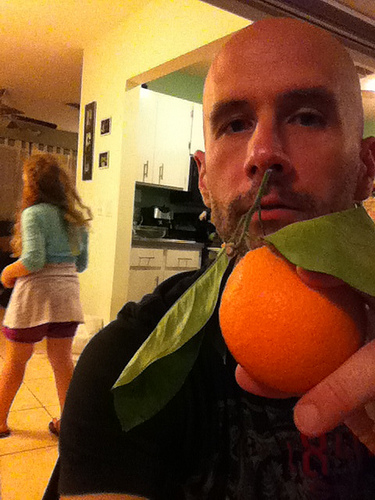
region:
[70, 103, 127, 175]
pictures on yellow wall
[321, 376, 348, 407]
ridges in man's finger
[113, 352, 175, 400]
edge of green leaf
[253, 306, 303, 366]
small grooves in orange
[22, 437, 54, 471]
tiles on floor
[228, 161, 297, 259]
stem of green leaf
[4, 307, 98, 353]
woman wearing purple shorts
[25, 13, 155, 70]
ridge in yellow ceiling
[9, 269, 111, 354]
woman wearing gray skirt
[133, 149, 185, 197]
the gold handle on yellow cabinet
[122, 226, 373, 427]
An orange with leaves on the stem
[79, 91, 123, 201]
Three pictures on the wall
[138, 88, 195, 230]
White cabinets on a blue wall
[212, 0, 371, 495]
A man with a black shirt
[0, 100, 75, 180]
White curtains are hanging in the room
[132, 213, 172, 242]
A clear bowl sits on the counter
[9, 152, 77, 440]
A woman in pink is walking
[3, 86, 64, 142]
The room has a ceiling fan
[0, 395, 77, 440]
The woman is wearing sandles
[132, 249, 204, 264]
The cabinets have silver handles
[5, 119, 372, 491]
The picture has an orange in it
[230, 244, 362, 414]
The orange is orange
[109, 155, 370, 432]
The orange has leaves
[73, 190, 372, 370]
The orange has green leaves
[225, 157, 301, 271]
The orange has a stem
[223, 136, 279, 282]
The orange has a green stem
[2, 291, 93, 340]
The girl is wearing shorts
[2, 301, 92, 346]
The girl is wearing magenta colored shorts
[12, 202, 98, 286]
The girl is wearing a shirt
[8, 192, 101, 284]
The girl is wearing a blue shirt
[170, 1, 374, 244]
Man looking at the camera.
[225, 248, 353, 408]
The man is holding an orange.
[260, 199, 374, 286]
The orange has green leaves.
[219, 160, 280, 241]
The orange's stem is green.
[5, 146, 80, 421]
A woman in the background.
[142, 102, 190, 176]
The cabinets are white.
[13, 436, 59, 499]
The floor is tile.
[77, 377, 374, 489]
The man's shirt is mostly black.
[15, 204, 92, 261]
The shirt is light blue.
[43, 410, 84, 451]
The woman is wearing sandals.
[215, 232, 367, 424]
Orange in man's hand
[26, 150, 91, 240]
Hair of lady walking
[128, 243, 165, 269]
Small kitchen drawer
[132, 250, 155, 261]
Handle on small beig drawer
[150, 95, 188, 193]
Left leg of lady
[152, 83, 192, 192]
Left beige cabinet door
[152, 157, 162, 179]
Left door handle of cabinet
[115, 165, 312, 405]
Green leaf in nose of man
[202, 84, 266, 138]
Right eye of man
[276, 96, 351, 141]
Left eye of man